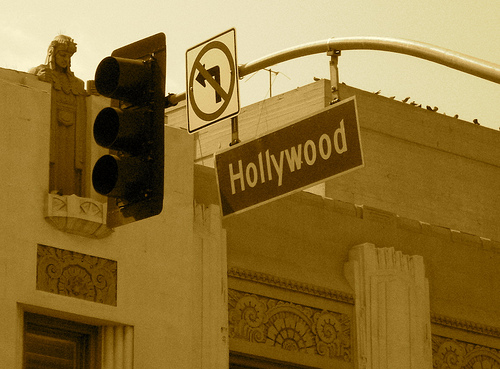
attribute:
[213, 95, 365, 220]
sign — hanging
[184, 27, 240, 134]
no-left-turn sign — hanging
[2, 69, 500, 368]
building — detailed, stone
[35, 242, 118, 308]
details — carved, ornate, inlaid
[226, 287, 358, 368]
details — carved, ornate, inlaid, large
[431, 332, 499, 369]
details — carved, ornate, inlaid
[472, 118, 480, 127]
bird — perched, sitting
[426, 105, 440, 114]
bird — perched, sitting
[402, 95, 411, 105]
bird — perched, sitting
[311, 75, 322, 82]
bird — perched, sitting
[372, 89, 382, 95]
bird — perched, sitting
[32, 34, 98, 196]
statue — stone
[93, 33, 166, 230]
traffic signal — black, hanging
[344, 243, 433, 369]
pillar — carved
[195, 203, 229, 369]
pillar — carved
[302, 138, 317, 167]
letter o — white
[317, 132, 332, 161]
letter o — white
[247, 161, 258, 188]
letter o — white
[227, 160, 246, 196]
letter h — white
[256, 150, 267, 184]
letter l — white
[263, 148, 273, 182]
letter l — white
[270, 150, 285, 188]
y — white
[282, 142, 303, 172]
w — white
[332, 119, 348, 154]
d — white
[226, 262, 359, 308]
design — post-modern